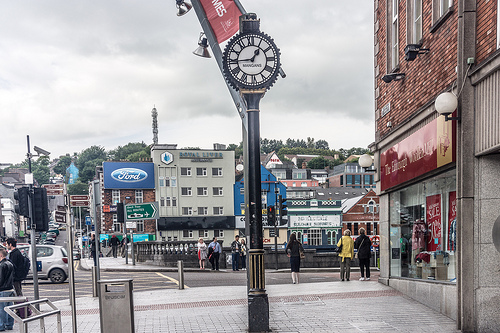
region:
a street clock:
[204, 16, 296, 112]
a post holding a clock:
[206, 10, 315, 330]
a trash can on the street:
[79, 255, 153, 330]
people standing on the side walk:
[277, 225, 402, 287]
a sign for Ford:
[83, 138, 164, 208]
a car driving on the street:
[6, 224, 91, 293]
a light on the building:
[421, 67, 482, 146]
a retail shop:
[361, 120, 477, 322]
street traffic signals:
[9, 150, 57, 280]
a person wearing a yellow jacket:
[329, 217, 364, 292]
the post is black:
[233, 153, 305, 313]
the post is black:
[244, 216, 307, 329]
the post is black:
[236, 211, 283, 316]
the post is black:
[230, 236, 271, 312]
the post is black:
[173, 85, 309, 321]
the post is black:
[185, 122, 265, 308]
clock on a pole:
[216, 22, 289, 105]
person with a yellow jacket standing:
[332, 225, 357, 285]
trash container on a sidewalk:
[92, 271, 144, 332]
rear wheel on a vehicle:
[45, 262, 70, 285]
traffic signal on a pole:
[8, 178, 36, 225]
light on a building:
[432, 89, 467, 127]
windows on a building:
[192, 163, 227, 181]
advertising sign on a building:
[97, 156, 159, 193]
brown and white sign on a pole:
[64, 188, 95, 213]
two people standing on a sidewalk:
[194, 232, 227, 275]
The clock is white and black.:
[201, 18, 295, 98]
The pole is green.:
[205, 6, 304, 323]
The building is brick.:
[397, 58, 443, 107]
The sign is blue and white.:
[85, 153, 185, 208]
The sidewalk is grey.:
[162, 301, 324, 329]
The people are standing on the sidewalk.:
[275, 212, 392, 294]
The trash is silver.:
[83, 273, 153, 330]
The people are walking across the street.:
[157, 232, 257, 273]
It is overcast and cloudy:
[11, 10, 127, 130]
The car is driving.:
[10, 236, 82, 292]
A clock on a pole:
[208, 10, 290, 330]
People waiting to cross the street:
[281, 222, 381, 284]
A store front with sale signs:
[336, 113, 491, 314]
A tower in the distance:
[145, 95, 166, 147]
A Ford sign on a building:
[98, 155, 158, 190]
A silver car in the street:
[4, 239, 72, 282]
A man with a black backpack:
[4, 230, 37, 295]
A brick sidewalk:
[156, 300, 462, 330]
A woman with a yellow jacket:
[332, 220, 358, 280]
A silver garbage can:
[87, 265, 161, 332]